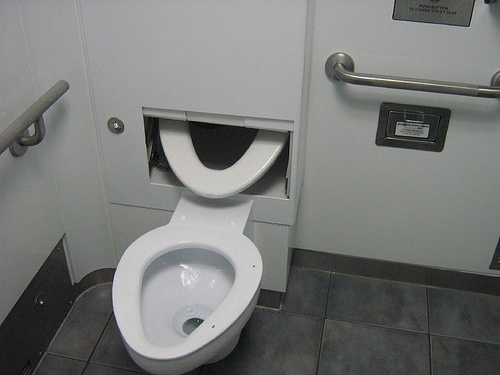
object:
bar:
[333, 63, 500, 99]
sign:
[392, 0, 476, 27]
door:
[386, 110, 440, 142]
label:
[395, 121, 430, 138]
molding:
[291, 246, 500, 296]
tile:
[324, 266, 430, 334]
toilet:
[107, 197, 265, 375]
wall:
[297, 0, 500, 296]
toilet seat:
[156, 117, 290, 199]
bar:
[0, 79, 70, 157]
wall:
[0, 0, 78, 373]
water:
[175, 309, 210, 338]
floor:
[29, 260, 499, 375]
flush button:
[107, 117, 124, 134]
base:
[207, 331, 241, 364]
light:
[176, 262, 220, 289]